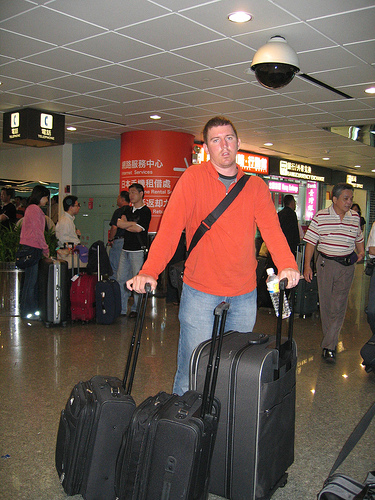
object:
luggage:
[54, 281, 153, 499]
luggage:
[114, 301, 233, 499]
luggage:
[188, 275, 298, 500]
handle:
[122, 282, 153, 392]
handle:
[200, 300, 230, 419]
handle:
[275, 276, 295, 353]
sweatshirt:
[137, 159, 299, 297]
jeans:
[172, 282, 258, 398]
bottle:
[265, 267, 292, 320]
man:
[303, 182, 365, 364]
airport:
[0, 0, 375, 497]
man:
[125, 115, 301, 397]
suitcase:
[70, 247, 97, 327]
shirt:
[303, 202, 365, 257]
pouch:
[319, 250, 361, 266]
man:
[116, 183, 152, 319]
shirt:
[116, 204, 152, 252]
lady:
[20, 182, 51, 321]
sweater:
[19, 203, 49, 253]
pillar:
[120, 129, 195, 297]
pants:
[316, 256, 355, 350]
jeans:
[21, 250, 39, 314]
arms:
[116, 205, 151, 232]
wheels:
[69, 320, 88, 326]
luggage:
[40, 256, 69, 328]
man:
[55, 195, 81, 246]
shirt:
[54, 212, 81, 250]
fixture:
[227, 11, 254, 24]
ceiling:
[0, 1, 375, 177]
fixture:
[149, 114, 161, 120]